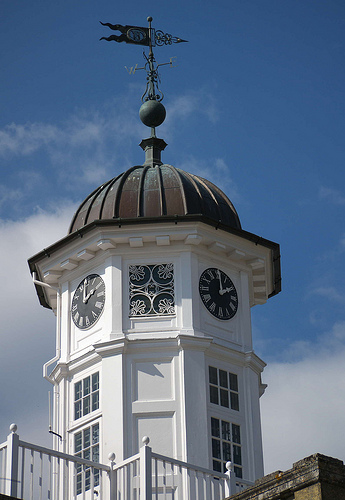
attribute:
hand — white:
[82, 278, 87, 304]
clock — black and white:
[69, 273, 105, 330]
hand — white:
[82, 278, 93, 303]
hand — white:
[216, 270, 222, 296]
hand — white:
[216, 271, 233, 295]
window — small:
[196, 361, 258, 428]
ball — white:
[136, 430, 177, 453]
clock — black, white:
[192, 269, 271, 328]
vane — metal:
[135, 0, 170, 137]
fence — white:
[2, 416, 180, 473]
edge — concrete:
[254, 456, 337, 472]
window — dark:
[128, 261, 182, 320]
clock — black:
[64, 263, 139, 330]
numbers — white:
[70, 293, 130, 309]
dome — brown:
[51, 137, 247, 227]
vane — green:
[125, 3, 190, 139]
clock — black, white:
[180, 264, 284, 338]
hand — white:
[215, 272, 224, 292]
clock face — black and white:
[198, 265, 239, 319]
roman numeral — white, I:
[221, 273, 231, 288]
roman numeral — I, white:
[89, 276, 97, 286]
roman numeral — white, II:
[228, 284, 235, 293]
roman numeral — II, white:
[94, 281, 104, 291]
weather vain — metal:
[98, 12, 190, 99]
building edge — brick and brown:
[257, 458, 315, 483]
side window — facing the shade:
[205, 359, 250, 481]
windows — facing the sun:
[68, 368, 101, 495]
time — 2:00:
[80, 277, 104, 303]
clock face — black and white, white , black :
[68, 271, 106, 331]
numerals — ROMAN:
[72, 299, 92, 327]